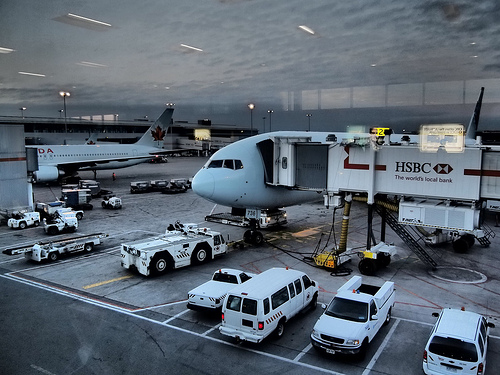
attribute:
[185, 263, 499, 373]
vehicles — white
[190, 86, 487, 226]
airplane — white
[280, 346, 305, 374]
lines — white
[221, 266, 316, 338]
commercial van — white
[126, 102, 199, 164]
maple leaf — red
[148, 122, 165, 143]
leaf — red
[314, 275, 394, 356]
truck — white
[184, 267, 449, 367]
white vehicles — white 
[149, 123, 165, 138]
maple leaf — red